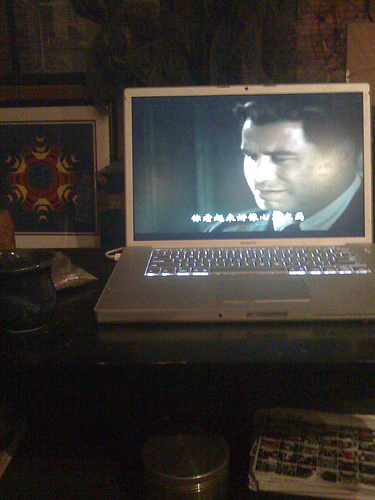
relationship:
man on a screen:
[197, 97, 365, 232] [130, 94, 364, 239]